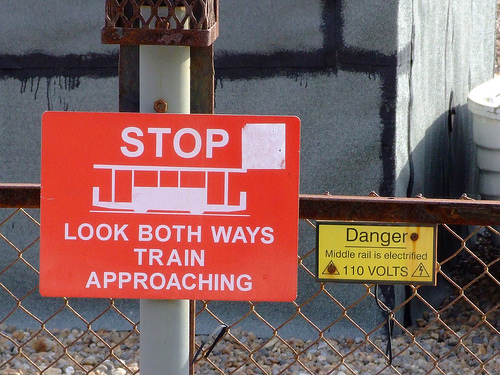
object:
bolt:
[154, 99, 167, 112]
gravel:
[0, 334, 496, 373]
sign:
[316, 220, 437, 285]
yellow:
[319, 225, 345, 249]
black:
[316, 221, 319, 282]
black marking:
[0, 50, 397, 78]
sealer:
[0, 0, 398, 339]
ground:
[0, 330, 499, 375]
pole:
[139, 45, 189, 373]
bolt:
[410, 233, 417, 241]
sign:
[39, 112, 298, 300]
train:
[132, 186, 207, 214]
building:
[0, 0, 499, 339]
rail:
[298, 194, 500, 225]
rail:
[1, 183, 43, 208]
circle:
[447, 91, 457, 132]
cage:
[0, 183, 498, 375]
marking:
[321, 260, 339, 275]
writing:
[85, 271, 252, 292]